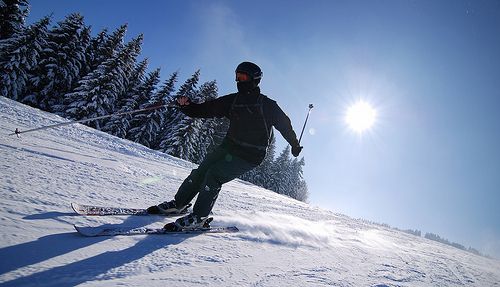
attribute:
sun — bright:
[343, 100, 378, 133]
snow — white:
[252, 247, 423, 280]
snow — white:
[70, 140, 131, 183]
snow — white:
[12, 235, 341, 285]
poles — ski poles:
[11, 87, 342, 168]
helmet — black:
[231, 56, 267, 79]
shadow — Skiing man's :
[0, 215, 210, 285]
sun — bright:
[313, 90, 398, 155]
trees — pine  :
[73, 33, 144, 112]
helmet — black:
[231, 63, 275, 115]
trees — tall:
[16, 10, 156, 148]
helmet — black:
[234, 60, 263, 87]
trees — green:
[24, 12, 174, 135]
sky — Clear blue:
[50, 3, 499, 243]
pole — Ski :
[7, 97, 187, 158]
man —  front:
[149, 60, 303, 232]